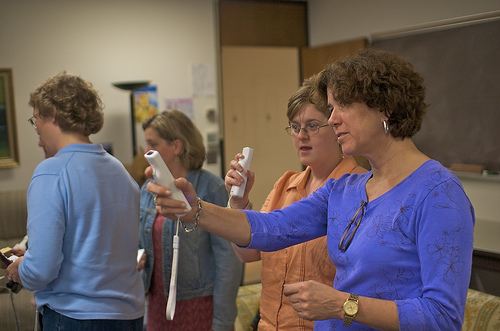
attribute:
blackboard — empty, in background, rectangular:
[368, 12, 499, 182]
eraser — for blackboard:
[481, 169, 499, 175]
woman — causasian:
[145, 46, 479, 330]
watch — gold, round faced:
[340, 290, 360, 327]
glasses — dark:
[338, 200, 368, 252]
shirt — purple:
[237, 156, 475, 329]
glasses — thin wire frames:
[285, 121, 334, 138]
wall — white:
[1, 1, 308, 196]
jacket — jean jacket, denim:
[137, 167, 243, 329]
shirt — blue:
[18, 144, 146, 321]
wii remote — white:
[144, 145, 193, 218]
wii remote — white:
[229, 145, 256, 199]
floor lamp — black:
[112, 80, 150, 161]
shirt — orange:
[257, 154, 372, 330]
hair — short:
[315, 50, 430, 140]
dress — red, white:
[146, 213, 238, 330]